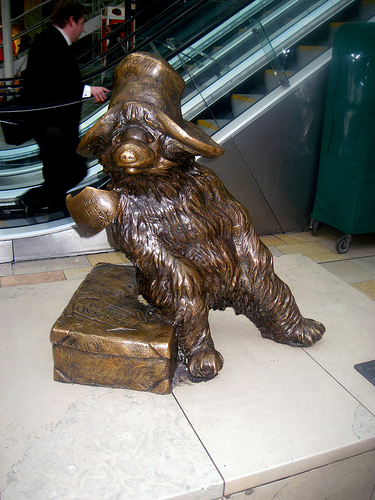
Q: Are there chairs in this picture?
A: No, there are no chairs.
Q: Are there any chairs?
A: No, there are no chairs.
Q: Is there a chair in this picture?
A: No, there are no chairs.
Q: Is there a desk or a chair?
A: No, there are no chairs or desks.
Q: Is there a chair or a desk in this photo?
A: No, there are no chairs or desks.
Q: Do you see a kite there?
A: No, there are no kites.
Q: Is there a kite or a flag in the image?
A: No, there are no kites or flags.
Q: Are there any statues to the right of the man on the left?
A: Yes, there is a statue to the right of the man.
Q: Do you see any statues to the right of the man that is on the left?
A: Yes, there is a statue to the right of the man.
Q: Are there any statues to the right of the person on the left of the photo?
A: Yes, there is a statue to the right of the man.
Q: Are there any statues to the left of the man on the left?
A: No, the statue is to the right of the man.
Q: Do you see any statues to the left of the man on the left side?
A: No, the statue is to the right of the man.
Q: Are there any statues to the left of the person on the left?
A: No, the statue is to the right of the man.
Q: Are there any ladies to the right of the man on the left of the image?
A: No, there is a statue to the right of the man.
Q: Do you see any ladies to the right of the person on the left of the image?
A: No, there is a statue to the right of the man.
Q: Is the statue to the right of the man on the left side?
A: Yes, the statue is to the right of the man.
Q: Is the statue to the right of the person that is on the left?
A: Yes, the statue is to the right of the man.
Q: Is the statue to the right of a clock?
A: No, the statue is to the right of the man.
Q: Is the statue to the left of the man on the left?
A: No, the statue is to the right of the man.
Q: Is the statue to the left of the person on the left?
A: No, the statue is to the right of the man.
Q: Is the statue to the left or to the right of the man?
A: The statue is to the right of the man.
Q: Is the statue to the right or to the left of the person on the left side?
A: The statue is to the right of the man.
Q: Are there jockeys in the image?
A: No, there are no jockeys.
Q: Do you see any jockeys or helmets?
A: No, there are no jockeys or helmets.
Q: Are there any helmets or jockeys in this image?
A: No, there are no jockeys or helmets.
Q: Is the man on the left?
A: Yes, the man is on the left of the image.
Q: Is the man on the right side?
A: No, the man is on the left of the image.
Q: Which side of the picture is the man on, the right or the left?
A: The man is on the left of the image.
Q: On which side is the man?
A: The man is on the left of the image.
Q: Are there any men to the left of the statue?
A: Yes, there is a man to the left of the statue.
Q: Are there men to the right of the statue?
A: No, the man is to the left of the statue.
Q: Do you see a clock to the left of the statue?
A: No, there is a man to the left of the statue.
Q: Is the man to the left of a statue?
A: Yes, the man is to the left of a statue.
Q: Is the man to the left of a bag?
A: No, the man is to the left of a statue.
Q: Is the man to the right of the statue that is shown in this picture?
A: No, the man is to the left of the statue.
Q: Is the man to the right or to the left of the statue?
A: The man is to the left of the statue.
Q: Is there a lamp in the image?
A: No, there are no lamps.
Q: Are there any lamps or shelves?
A: No, there are no lamps or shelves.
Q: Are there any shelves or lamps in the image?
A: No, there are no lamps or shelves.